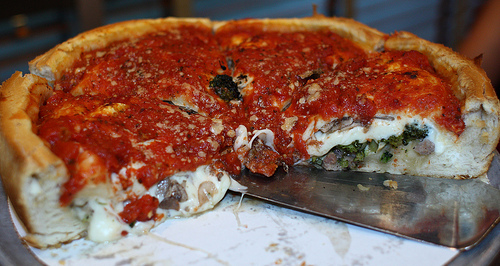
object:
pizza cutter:
[231, 159, 496, 234]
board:
[227, 143, 500, 252]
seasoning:
[85, 50, 261, 139]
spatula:
[277, 162, 499, 255]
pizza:
[0, 4, 499, 252]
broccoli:
[343, 145, 364, 158]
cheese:
[367, 120, 396, 136]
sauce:
[255, 37, 304, 61]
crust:
[1, 70, 91, 250]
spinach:
[386, 136, 414, 148]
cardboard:
[7, 196, 460, 265]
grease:
[314, 223, 354, 258]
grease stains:
[266, 241, 309, 265]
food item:
[210, 72, 241, 101]